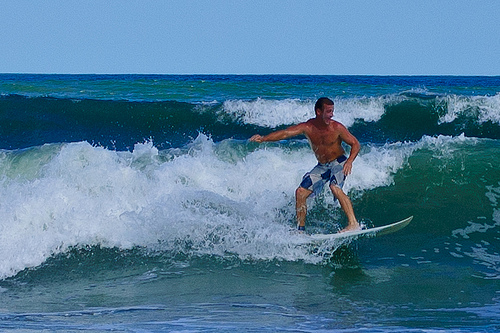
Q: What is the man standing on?
A: Surf board.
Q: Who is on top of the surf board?
A: The man.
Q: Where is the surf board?
A: In the water.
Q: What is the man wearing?
A: Swimming trunks.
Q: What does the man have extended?
A: His arm.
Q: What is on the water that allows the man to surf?
A: Wave.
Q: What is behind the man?
A: Wave.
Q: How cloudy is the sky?
A: It is clear.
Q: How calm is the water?
A: It has waves.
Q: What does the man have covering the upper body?
A: Nothing.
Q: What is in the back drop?
A: Blue sky.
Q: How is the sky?
A: With no clouds.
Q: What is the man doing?
A: Surfing.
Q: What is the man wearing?
A: Shorts.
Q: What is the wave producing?
A: Foam.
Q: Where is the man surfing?
A: On a wave.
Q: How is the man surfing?
A: Standing up.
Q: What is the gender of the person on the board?
A: A man.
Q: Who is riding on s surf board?
A: A surfer.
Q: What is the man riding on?
A: A surf board.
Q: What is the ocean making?
A: Waves.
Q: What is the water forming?
A: Waves.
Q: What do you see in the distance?
A: Clear blue sky.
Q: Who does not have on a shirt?
A: A surfer.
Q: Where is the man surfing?
A: The ocean.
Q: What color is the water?
A: Blue.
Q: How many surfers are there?
A: 1.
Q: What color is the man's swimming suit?
A: White and blue.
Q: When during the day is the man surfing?
A: During the day.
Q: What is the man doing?
A: Surfing.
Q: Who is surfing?
A: A man.